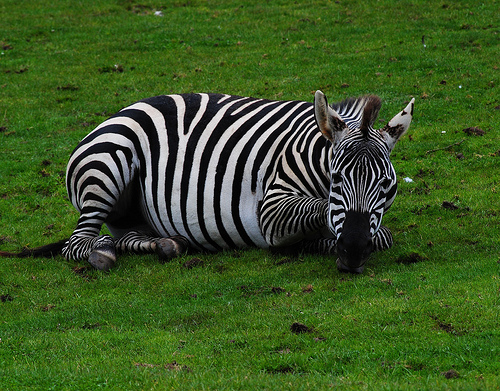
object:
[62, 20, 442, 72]
grass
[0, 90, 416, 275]
zebra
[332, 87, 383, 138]
mane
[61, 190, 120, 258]
legs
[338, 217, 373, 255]
nose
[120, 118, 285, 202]
stripes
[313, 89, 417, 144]
ears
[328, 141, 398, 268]
face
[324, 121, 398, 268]
head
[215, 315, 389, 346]
dirt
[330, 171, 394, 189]
eyes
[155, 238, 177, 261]
hoof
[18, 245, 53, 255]
hair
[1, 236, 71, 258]
tail